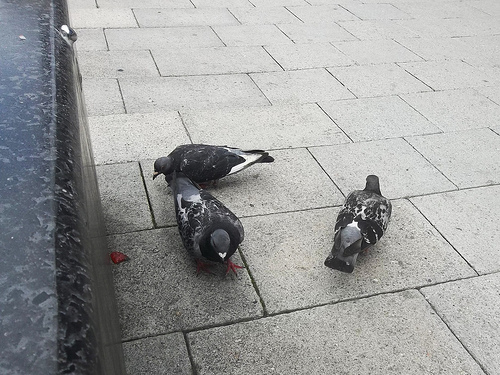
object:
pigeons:
[323, 174, 398, 274]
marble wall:
[1, 0, 117, 373]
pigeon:
[147, 138, 275, 183]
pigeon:
[324, 174, 392, 272]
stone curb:
[0, 0, 125, 375]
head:
[210, 227, 231, 263]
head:
[365, 174, 380, 195]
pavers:
[72, 21, 272, 98]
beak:
[151, 172, 162, 181]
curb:
[0, 0, 129, 375]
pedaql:
[109, 248, 131, 266]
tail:
[249, 149, 274, 163]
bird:
[148, 141, 276, 192]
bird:
[173, 172, 248, 277]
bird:
[323, 174, 393, 274]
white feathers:
[353, 223, 356, 227]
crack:
[179, 325, 200, 372]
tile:
[54, 0, 500, 372]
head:
[151, 157, 169, 181]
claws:
[183, 257, 246, 278]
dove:
[151, 142, 274, 189]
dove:
[166, 172, 248, 277]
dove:
[323, 174, 393, 274]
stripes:
[358, 205, 368, 224]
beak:
[217, 251, 227, 263]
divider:
[0, 0, 127, 372]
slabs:
[78, 3, 499, 375]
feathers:
[323, 174, 392, 274]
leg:
[225, 252, 247, 279]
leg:
[191, 247, 218, 276]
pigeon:
[169, 173, 246, 280]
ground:
[2, 0, 497, 372]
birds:
[151, 144, 276, 192]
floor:
[62, 0, 500, 372]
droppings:
[60, 23, 71, 34]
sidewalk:
[82, 49, 500, 373]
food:
[366, 277, 383, 287]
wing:
[330, 190, 393, 256]